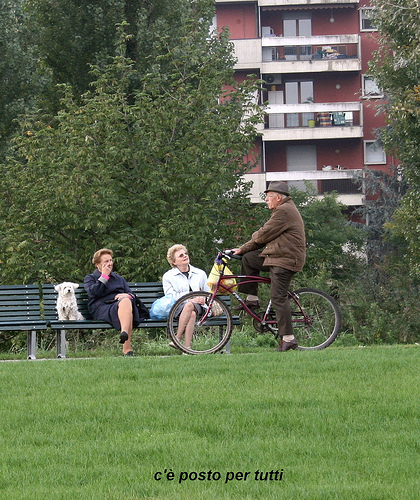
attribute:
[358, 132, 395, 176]
window — small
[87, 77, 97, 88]
leaves — green 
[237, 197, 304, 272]
jacket — brown